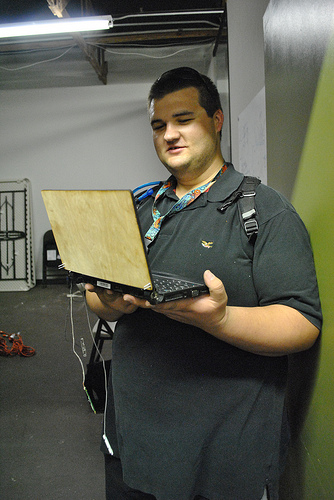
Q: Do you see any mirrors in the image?
A: No, there are no mirrors.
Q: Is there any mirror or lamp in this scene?
A: No, there are no mirrors or lamps.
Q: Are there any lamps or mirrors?
A: No, there are no mirrors or lamps.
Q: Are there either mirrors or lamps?
A: No, there are no mirrors or lamps.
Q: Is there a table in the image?
A: Yes, there is a table.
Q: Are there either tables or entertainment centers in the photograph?
A: Yes, there is a table.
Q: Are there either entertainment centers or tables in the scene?
A: Yes, there is a table.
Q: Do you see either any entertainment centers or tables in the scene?
A: Yes, there is a table.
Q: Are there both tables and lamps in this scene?
A: No, there is a table but no lamps.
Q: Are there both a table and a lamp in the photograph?
A: No, there is a table but no lamps.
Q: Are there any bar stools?
A: No, there are no bar stools.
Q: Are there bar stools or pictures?
A: No, there are no bar stools or pictures.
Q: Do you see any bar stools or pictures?
A: No, there are no bar stools or pictures.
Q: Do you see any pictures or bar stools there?
A: No, there are no bar stools or pictures.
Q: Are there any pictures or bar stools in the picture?
A: No, there are no bar stools or pictures.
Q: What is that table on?
A: The table is on the wall.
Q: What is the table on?
A: The table is on the wall.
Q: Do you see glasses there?
A: No, there are no glasses.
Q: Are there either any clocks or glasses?
A: No, there are no glasses or clocks.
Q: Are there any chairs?
A: Yes, there is a chair.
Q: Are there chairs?
A: Yes, there is a chair.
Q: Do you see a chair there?
A: Yes, there is a chair.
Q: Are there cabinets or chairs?
A: Yes, there is a chair.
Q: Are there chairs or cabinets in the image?
A: Yes, there is a chair.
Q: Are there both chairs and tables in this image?
A: Yes, there are both a chair and a table.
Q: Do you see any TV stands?
A: No, there are no TV stands.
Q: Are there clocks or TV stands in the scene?
A: No, there are no TV stands or clocks.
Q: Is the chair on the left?
A: Yes, the chair is on the left of the image.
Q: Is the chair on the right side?
A: No, the chair is on the left of the image.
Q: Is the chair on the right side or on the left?
A: The chair is on the left of the image.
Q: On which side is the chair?
A: The chair is on the left of the image.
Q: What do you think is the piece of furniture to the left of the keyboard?
A: The piece of furniture is a chair.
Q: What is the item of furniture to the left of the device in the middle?
A: The piece of furniture is a chair.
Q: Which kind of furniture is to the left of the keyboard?
A: The piece of furniture is a chair.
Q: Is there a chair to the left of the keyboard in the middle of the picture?
A: Yes, there is a chair to the left of the keyboard.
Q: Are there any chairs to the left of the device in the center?
A: Yes, there is a chair to the left of the keyboard.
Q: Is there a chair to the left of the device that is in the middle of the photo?
A: Yes, there is a chair to the left of the keyboard.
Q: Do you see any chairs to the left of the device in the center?
A: Yes, there is a chair to the left of the keyboard.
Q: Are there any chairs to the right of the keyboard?
A: No, the chair is to the left of the keyboard.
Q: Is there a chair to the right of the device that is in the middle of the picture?
A: No, the chair is to the left of the keyboard.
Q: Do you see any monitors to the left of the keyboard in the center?
A: No, there is a chair to the left of the keyboard.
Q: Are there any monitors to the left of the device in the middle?
A: No, there is a chair to the left of the keyboard.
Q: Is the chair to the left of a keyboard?
A: Yes, the chair is to the left of a keyboard.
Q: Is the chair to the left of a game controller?
A: No, the chair is to the left of a keyboard.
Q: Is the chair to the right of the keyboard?
A: No, the chair is to the left of the keyboard.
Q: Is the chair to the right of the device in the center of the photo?
A: No, the chair is to the left of the keyboard.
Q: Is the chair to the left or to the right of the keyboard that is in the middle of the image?
A: The chair is to the left of the keyboard.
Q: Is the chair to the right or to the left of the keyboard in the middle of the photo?
A: The chair is to the left of the keyboard.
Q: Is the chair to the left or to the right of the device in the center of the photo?
A: The chair is to the left of the keyboard.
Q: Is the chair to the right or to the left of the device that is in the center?
A: The chair is to the left of the keyboard.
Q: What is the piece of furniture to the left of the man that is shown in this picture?
A: The piece of furniture is a chair.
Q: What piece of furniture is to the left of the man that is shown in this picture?
A: The piece of furniture is a chair.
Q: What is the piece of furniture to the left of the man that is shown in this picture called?
A: The piece of furniture is a chair.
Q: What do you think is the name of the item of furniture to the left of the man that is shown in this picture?
A: The piece of furniture is a chair.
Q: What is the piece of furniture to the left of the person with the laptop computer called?
A: The piece of furniture is a chair.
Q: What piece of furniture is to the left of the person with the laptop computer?
A: The piece of furniture is a chair.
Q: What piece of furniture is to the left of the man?
A: The piece of furniture is a chair.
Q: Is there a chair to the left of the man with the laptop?
A: Yes, there is a chair to the left of the man.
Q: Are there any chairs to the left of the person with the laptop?
A: Yes, there is a chair to the left of the man.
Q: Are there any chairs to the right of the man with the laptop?
A: No, the chair is to the left of the man.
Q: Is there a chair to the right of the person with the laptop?
A: No, the chair is to the left of the man.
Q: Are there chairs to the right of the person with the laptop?
A: No, the chair is to the left of the man.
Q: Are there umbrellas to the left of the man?
A: No, there is a chair to the left of the man.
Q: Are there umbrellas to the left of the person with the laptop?
A: No, there is a chair to the left of the man.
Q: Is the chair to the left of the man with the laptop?
A: Yes, the chair is to the left of the man.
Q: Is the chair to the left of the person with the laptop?
A: Yes, the chair is to the left of the man.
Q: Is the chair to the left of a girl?
A: No, the chair is to the left of the man.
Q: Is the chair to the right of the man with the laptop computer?
A: No, the chair is to the left of the man.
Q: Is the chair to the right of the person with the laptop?
A: No, the chair is to the left of the man.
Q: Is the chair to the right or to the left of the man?
A: The chair is to the left of the man.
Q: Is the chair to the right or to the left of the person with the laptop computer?
A: The chair is to the left of the man.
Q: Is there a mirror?
A: No, there are no mirrors.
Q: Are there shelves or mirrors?
A: No, there are no mirrors or shelves.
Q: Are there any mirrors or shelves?
A: No, there are no mirrors or shelves.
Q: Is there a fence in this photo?
A: No, there are no fences.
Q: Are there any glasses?
A: No, there are no glasses.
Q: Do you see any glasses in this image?
A: No, there are no glasses.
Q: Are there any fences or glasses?
A: No, there are no glasses or fences.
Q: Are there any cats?
A: No, there are no cats.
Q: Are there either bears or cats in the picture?
A: No, there are no cats or bears.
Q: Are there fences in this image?
A: No, there are no fences.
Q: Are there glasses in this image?
A: No, there are no glasses.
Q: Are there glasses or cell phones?
A: No, there are no glasses or cell phones.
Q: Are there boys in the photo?
A: No, there are no boys.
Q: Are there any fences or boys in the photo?
A: No, there are no boys or fences.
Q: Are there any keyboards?
A: Yes, there is a keyboard.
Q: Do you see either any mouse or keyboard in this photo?
A: Yes, there is a keyboard.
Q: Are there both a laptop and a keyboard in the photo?
A: Yes, there are both a keyboard and a laptop.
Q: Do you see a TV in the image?
A: No, there are no televisions.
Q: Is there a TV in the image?
A: No, there are no televisions.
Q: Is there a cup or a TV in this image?
A: No, there are no televisions or cups.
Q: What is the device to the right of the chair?
A: The device is a keyboard.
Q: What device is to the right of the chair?
A: The device is a keyboard.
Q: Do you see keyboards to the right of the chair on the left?
A: Yes, there is a keyboard to the right of the chair.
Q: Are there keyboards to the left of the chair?
A: No, the keyboard is to the right of the chair.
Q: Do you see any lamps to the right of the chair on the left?
A: No, there is a keyboard to the right of the chair.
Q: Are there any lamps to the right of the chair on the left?
A: No, there is a keyboard to the right of the chair.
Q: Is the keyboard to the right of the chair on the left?
A: Yes, the keyboard is to the right of the chair.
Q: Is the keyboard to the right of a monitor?
A: No, the keyboard is to the right of the chair.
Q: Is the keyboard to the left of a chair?
A: No, the keyboard is to the right of a chair.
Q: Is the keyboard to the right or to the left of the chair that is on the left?
A: The keyboard is to the right of the chair.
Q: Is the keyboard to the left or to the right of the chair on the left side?
A: The keyboard is to the right of the chair.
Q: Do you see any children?
A: No, there are no children.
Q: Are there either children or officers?
A: No, there are no children or officers.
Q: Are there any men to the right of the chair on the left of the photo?
A: Yes, there is a man to the right of the chair.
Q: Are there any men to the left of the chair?
A: No, the man is to the right of the chair.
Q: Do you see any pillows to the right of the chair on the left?
A: No, there is a man to the right of the chair.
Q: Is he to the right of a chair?
A: Yes, the man is to the right of a chair.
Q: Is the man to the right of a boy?
A: No, the man is to the right of a chair.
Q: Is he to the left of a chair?
A: No, the man is to the right of a chair.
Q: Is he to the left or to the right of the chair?
A: The man is to the right of the chair.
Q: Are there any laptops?
A: Yes, there is a laptop.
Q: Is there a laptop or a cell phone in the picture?
A: Yes, there is a laptop.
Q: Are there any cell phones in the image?
A: No, there are no cell phones.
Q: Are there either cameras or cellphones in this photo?
A: No, there are no cellphones or cameras.